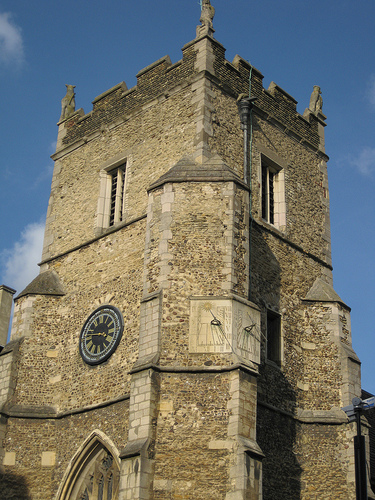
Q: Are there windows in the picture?
A: Yes, there is a window.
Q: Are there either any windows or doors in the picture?
A: Yes, there is a window.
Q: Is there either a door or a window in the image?
A: Yes, there is a window.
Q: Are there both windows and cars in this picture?
A: No, there is a window but no cars.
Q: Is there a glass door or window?
A: Yes, there is a glass window.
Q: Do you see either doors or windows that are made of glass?
A: Yes, the window is made of glass.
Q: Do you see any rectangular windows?
A: Yes, there is a rectangular window.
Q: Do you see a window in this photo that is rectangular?
A: Yes, there is a window that is rectangular.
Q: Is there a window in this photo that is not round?
A: Yes, there is a rectangular window.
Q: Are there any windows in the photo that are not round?
A: Yes, there is a rectangular window.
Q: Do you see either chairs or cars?
A: No, there are no cars or chairs.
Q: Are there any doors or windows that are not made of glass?
A: No, there is a window but it is made of glass.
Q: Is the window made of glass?
A: Yes, the window is made of glass.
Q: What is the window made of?
A: The window is made of glass.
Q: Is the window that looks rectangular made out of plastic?
A: No, the window is made of glass.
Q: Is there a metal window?
A: No, there is a window but it is made of glass.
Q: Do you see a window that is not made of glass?
A: No, there is a window but it is made of glass.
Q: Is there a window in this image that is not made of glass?
A: No, there is a window but it is made of glass.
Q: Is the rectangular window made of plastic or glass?
A: The window is made of glass.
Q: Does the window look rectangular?
A: Yes, the window is rectangular.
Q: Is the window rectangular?
A: Yes, the window is rectangular.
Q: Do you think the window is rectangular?
A: Yes, the window is rectangular.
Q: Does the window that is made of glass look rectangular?
A: Yes, the window is rectangular.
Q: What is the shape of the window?
A: The window is rectangular.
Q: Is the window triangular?
A: No, the window is rectangular.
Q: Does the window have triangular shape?
A: No, the window is rectangular.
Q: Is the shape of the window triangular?
A: No, the window is rectangular.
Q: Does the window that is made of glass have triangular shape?
A: No, the window is rectangular.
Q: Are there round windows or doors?
A: No, there is a window but it is rectangular.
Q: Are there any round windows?
A: No, there is a window but it is rectangular.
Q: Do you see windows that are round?
A: No, there is a window but it is rectangular.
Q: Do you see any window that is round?
A: No, there is a window but it is rectangular.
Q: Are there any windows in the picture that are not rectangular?
A: No, there is a window but it is rectangular.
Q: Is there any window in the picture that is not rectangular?
A: No, there is a window but it is rectangular.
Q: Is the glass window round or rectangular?
A: The window is rectangular.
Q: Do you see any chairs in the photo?
A: No, there are no chairs.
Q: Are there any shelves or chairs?
A: No, there are no chairs or shelves.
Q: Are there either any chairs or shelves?
A: No, there are no chairs or shelves.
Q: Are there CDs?
A: No, there are no cds.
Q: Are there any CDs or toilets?
A: No, there are no CDs or toilets.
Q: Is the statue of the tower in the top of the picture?
A: Yes, the statue is in the top of the image.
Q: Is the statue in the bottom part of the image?
A: No, the statue is in the top of the image.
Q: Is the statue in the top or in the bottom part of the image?
A: The statue is in the top of the image.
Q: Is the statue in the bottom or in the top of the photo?
A: The statue is in the top of the image.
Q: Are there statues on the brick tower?
A: Yes, there is a statue on the tower.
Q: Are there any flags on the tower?
A: No, there is a statue on the tower.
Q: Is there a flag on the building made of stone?
A: No, there is a statue on the tower.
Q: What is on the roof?
A: The statue is on the roof.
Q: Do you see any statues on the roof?
A: Yes, there is a statue on the roof.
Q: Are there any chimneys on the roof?
A: No, there is a statue on the roof.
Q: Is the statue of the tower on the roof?
A: Yes, the statue is on the roof.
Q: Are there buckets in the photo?
A: No, there are no buckets.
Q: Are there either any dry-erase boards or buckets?
A: No, there are no buckets or dry-erase boards.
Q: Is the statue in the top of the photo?
A: Yes, the statue is in the top of the image.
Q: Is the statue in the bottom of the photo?
A: No, the statue is in the top of the image.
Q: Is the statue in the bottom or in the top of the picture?
A: The statue is in the top of the image.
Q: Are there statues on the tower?
A: Yes, there is a statue on the tower.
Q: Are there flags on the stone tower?
A: No, there is a statue on the tower.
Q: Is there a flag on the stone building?
A: No, there is a statue on the tower.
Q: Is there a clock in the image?
A: Yes, there is a clock.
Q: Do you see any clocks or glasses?
A: Yes, there is a clock.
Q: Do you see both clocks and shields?
A: No, there is a clock but no shields.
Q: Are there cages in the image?
A: No, there are no cages.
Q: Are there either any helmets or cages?
A: No, there are no cages or helmets.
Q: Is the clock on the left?
A: Yes, the clock is on the left of the image.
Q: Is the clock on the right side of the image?
A: No, the clock is on the left of the image.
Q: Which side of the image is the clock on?
A: The clock is on the left of the image.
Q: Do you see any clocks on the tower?
A: Yes, there is a clock on the tower.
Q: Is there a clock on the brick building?
A: Yes, there is a clock on the tower.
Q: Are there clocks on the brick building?
A: Yes, there is a clock on the tower.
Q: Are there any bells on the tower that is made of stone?
A: No, there is a clock on the tower.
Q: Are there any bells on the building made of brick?
A: No, there is a clock on the tower.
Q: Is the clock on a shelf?
A: No, the clock is on the tower.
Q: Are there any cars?
A: No, there are no cars.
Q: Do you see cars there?
A: No, there are no cars.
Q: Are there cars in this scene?
A: No, there are no cars.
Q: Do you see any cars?
A: No, there are no cars.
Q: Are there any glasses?
A: No, there are no glasses.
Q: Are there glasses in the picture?
A: No, there are no glasses.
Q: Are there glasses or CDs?
A: No, there are no glasses or cds.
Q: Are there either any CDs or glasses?
A: No, there are no glasses or cds.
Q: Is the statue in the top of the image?
A: Yes, the statue is in the top of the image.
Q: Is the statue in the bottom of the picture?
A: No, the statue is in the top of the image.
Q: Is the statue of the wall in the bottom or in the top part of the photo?
A: The statue is in the top of the image.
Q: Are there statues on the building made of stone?
A: Yes, there is a statue on the tower.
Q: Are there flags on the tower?
A: No, there is a statue on the tower.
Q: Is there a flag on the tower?
A: No, there is a statue on the tower.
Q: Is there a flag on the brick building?
A: No, there is a statue on the tower.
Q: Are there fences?
A: No, there are no fences.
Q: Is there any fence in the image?
A: No, there are no fences.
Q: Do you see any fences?
A: No, there are no fences.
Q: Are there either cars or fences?
A: No, there are no fences or cars.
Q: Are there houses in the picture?
A: No, there are no houses.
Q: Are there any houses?
A: No, there are no houses.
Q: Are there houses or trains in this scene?
A: No, there are no houses or trains.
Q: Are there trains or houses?
A: No, there are no houses or trains.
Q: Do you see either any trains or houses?
A: No, there are no houses or trains.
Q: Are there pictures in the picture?
A: No, there are no pictures.